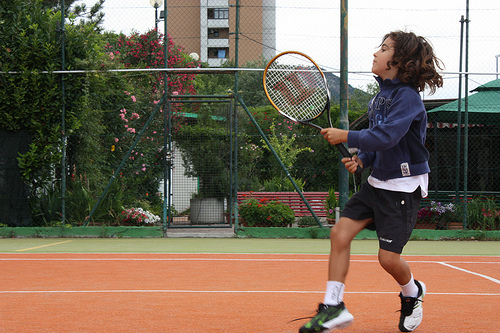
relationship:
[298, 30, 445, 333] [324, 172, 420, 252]
child wearing shorts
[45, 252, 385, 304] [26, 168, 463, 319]
line on court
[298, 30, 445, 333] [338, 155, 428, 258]
child wearing shorts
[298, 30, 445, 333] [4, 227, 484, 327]
child on court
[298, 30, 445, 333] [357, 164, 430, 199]
child wearing shirt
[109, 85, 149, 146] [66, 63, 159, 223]
flower on bushes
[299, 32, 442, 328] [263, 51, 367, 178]
child holding racket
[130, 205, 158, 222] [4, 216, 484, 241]
flower on ground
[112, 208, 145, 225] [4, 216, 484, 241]
flower on ground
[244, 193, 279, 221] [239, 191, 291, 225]
flowers on bush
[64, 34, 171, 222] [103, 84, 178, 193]
tree with flowers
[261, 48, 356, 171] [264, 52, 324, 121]
racket has strings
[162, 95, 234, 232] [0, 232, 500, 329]
door to enter tennis court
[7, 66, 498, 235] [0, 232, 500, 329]
fence around tennis court